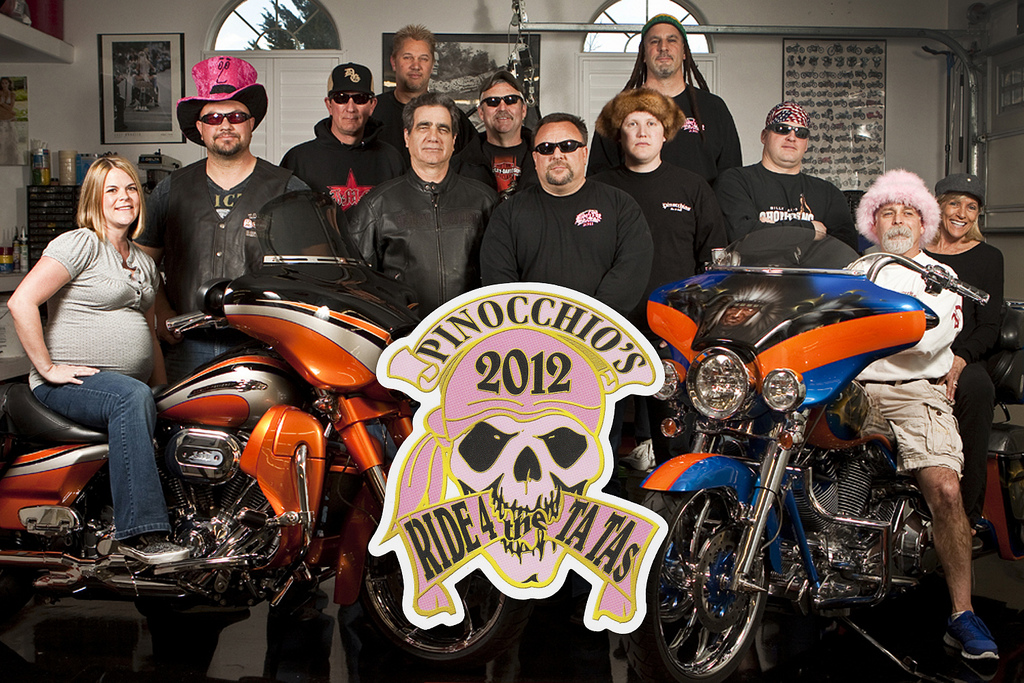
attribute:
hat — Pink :
[170, 47, 273, 139]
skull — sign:
[357, 262, 686, 645]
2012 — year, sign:
[473, 341, 578, 399]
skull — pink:
[354, 276, 672, 653]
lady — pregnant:
[10, 157, 198, 566]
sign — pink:
[376, 279, 667, 634]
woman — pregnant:
[5, 139, 198, 569]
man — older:
[824, 169, 1008, 660]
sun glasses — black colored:
[768, 122, 816, 149]